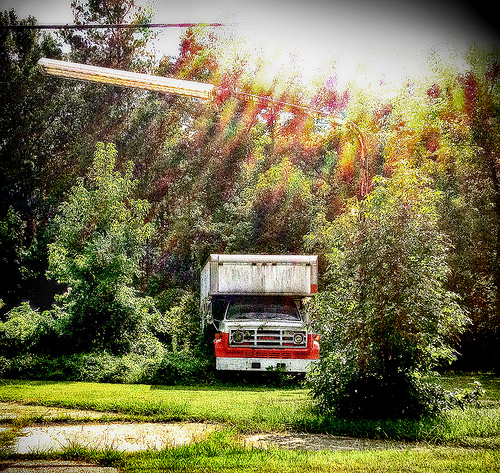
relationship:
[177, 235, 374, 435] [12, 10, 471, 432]
truck in forest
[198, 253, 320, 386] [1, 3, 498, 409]
truck in forest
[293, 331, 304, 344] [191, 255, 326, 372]
headlight in front of car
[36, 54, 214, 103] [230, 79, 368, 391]
light on a pole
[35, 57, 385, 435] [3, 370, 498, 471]
pole on a field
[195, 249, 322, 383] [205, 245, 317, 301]
truck has cargo space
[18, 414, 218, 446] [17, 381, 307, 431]
big gap in grass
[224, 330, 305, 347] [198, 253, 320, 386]
headlight on truck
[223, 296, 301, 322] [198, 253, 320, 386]
windshield of truck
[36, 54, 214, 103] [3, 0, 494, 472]
light in park